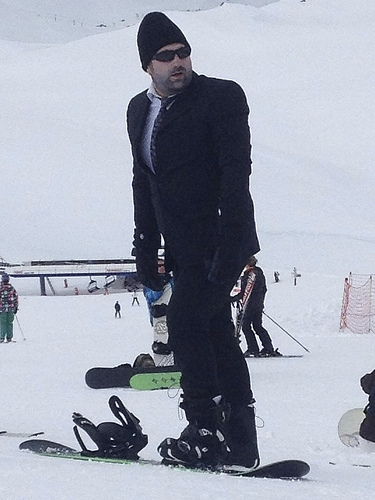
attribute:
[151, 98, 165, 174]
tie — dark colored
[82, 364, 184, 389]
snowboard — light green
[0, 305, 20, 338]
pants — green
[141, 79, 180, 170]
shirt — white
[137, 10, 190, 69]
cap — black, knit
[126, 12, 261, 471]
glasses — sunglasses, black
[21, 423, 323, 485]
snowboard — black, green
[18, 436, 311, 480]
snowboard — green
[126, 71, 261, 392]
suit — business suit